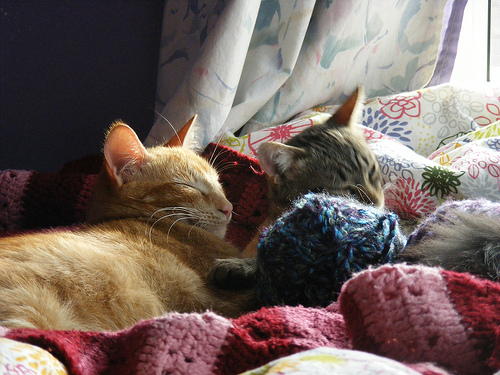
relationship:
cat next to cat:
[2, 112, 256, 374] [212, 85, 499, 316]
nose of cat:
[219, 200, 234, 218] [2, 112, 256, 374]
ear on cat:
[101, 118, 147, 185] [2, 112, 256, 374]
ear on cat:
[162, 113, 200, 150] [2, 112, 256, 374]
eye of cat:
[172, 178, 210, 199] [2, 112, 256, 374]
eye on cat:
[172, 178, 210, 199] [2, 112, 256, 374]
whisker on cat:
[145, 202, 201, 224] [2, 112, 256, 374]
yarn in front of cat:
[255, 190, 409, 308] [2, 112, 256, 374]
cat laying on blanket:
[2, 112, 256, 374] [3, 265, 499, 374]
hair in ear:
[266, 148, 293, 173] [258, 140, 306, 181]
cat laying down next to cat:
[2, 112, 256, 374] [212, 85, 499, 316]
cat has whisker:
[2, 112, 256, 374] [145, 202, 201, 224]